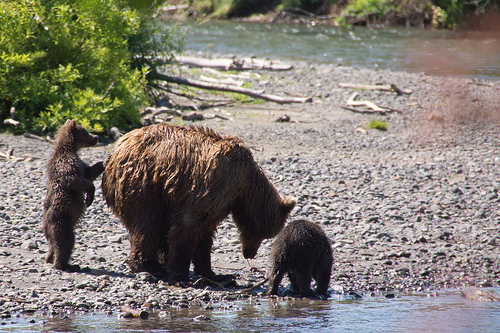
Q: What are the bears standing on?
A: Rocks.